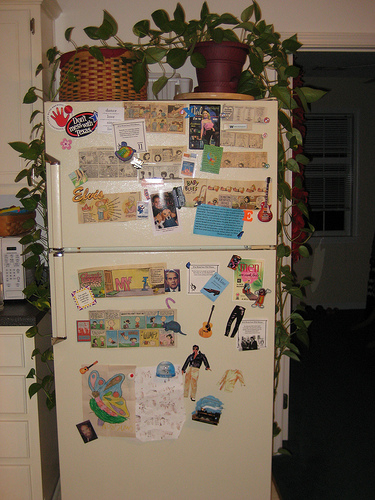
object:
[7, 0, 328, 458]
houseplant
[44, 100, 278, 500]
refrigerator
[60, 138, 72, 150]
magnet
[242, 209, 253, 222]
magnet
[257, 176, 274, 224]
magnet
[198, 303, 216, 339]
magnet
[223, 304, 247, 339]
magnet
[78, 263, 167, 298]
comics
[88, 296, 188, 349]
comics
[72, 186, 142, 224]
comics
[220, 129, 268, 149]
comics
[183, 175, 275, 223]
comics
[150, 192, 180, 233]
photo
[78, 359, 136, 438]
artwork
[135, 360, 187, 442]
artwork